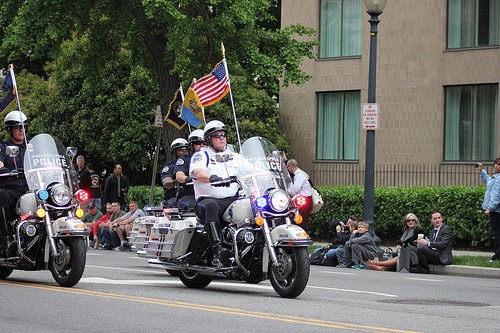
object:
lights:
[36, 188, 49, 201]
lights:
[74, 189, 89, 203]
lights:
[255, 196, 267, 208]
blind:
[443, 83, 500, 162]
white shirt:
[189, 144, 270, 201]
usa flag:
[190, 58, 229, 106]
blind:
[316, 90, 360, 160]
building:
[278, 0, 500, 187]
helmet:
[169, 138, 189, 160]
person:
[475, 156, 500, 262]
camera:
[474, 164, 479, 168]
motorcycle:
[135, 135, 315, 298]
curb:
[433, 265, 499, 279]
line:
[406, 277, 444, 282]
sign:
[360, 103, 380, 130]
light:
[268, 189, 290, 213]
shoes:
[368, 259, 383, 271]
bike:
[0, 133, 91, 287]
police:
[0, 110, 271, 266]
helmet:
[188, 129, 205, 152]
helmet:
[3, 110, 30, 141]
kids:
[314, 214, 378, 271]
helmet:
[203, 119, 228, 152]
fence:
[304, 161, 495, 185]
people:
[314, 210, 453, 273]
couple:
[368, 211, 453, 274]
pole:
[363, 10, 382, 247]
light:
[291, 194, 308, 207]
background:
[1, 0, 499, 118]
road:
[0, 248, 500, 333]